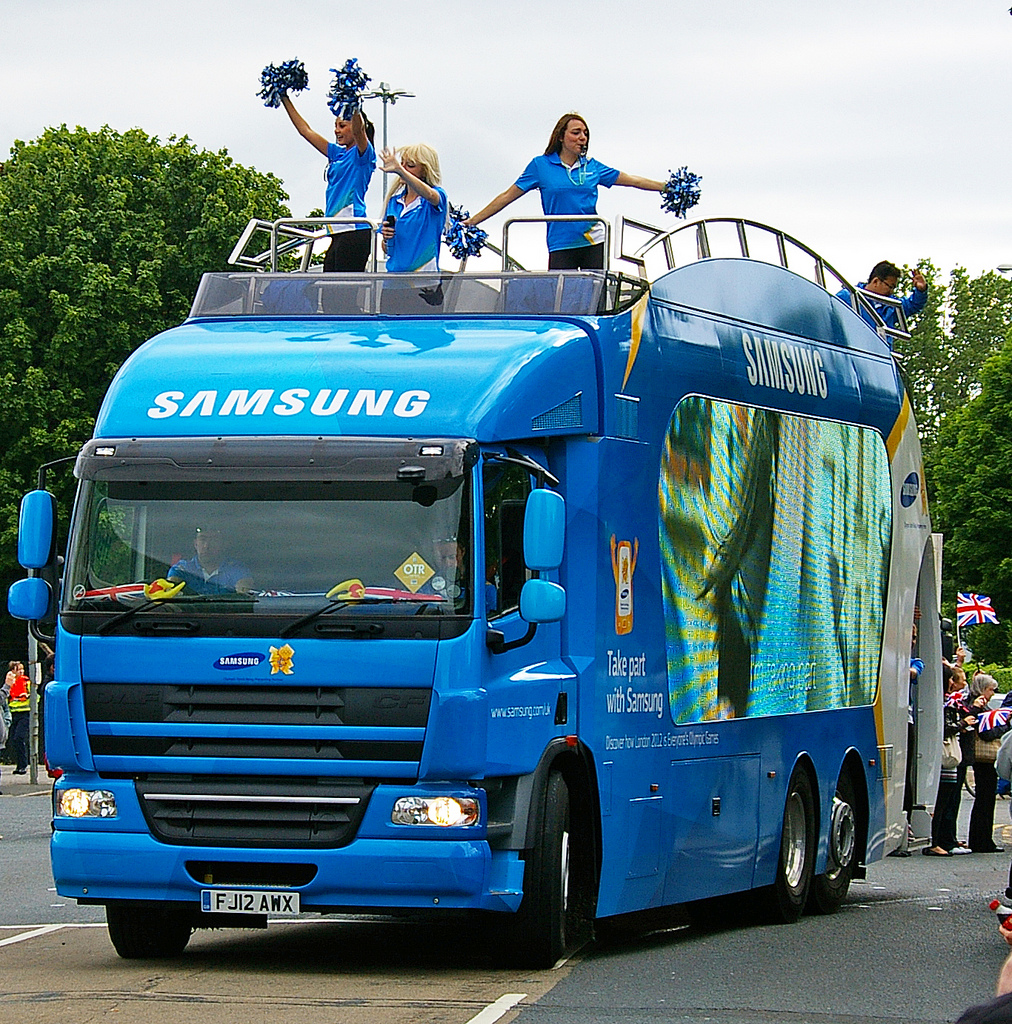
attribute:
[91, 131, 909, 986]
truck — blue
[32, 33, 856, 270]
sky — white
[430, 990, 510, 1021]
line — white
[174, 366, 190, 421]
letter — white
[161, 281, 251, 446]
letter — white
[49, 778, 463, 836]
headlights — pictured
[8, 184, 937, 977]
bus — blue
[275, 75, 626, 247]
people — blue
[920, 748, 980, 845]
pants — black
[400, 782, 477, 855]
bus —  head light 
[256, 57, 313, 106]
pom-poms — blue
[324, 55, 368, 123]
pom-poms — blue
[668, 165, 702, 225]
pom-poms — blue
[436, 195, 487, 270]
pom-poms — blue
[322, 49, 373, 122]
pom-poms — blue, blue and silver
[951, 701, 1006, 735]
flag — small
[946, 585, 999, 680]
flag — small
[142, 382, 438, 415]
lettering — white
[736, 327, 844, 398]
lettering — white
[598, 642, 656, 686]
lettering — white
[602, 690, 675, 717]
lettering — white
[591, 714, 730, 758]
lettering — white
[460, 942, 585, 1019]
line — white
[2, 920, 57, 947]
line — white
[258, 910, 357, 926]
line — white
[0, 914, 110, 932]
line — white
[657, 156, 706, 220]
pom-poms — blue and silver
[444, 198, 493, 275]
pom-poms — blue and silver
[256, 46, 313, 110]
pom-poms — blue and silver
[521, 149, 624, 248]
shirt — blue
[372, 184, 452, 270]
shirt — blue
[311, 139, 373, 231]
shirt — blue